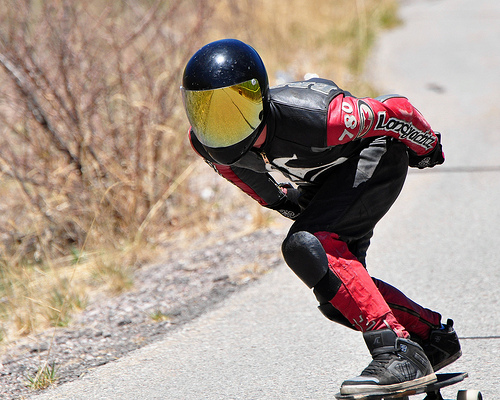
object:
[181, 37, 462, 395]
man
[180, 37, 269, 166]
helmet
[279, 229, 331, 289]
knee pads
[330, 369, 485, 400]
skateboard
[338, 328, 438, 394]
shoes